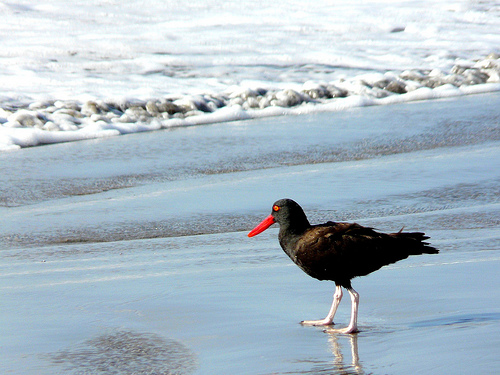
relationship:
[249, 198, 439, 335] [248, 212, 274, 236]
bird with red beak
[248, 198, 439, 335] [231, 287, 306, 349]
bird standing on sand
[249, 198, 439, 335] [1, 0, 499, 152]
bird near water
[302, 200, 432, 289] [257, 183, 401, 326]
feathers of a bird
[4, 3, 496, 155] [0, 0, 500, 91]
wave in ocean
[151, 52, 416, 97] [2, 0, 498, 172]
wave in ocean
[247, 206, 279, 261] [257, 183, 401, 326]
beak of a bird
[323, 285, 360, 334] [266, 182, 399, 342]
birds legs of a bird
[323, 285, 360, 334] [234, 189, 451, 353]
birds legs of a bird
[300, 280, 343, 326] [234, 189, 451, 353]
birds legs of a bird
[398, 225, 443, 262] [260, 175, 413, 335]
tail of a bird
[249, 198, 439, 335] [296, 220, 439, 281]
bird has wing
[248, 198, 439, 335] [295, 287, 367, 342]
bird has leg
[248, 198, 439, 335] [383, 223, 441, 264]
bird has tail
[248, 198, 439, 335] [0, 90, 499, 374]
bird on beach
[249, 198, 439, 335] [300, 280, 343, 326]
bird has birds legs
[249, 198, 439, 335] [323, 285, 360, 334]
bird has birds legs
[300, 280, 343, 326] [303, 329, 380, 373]
birds legs in reflection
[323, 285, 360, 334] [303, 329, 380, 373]
birds legs in reflection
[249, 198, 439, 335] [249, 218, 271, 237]
bird has beak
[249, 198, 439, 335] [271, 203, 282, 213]
bird has eye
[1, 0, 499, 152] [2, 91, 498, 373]
water on sand